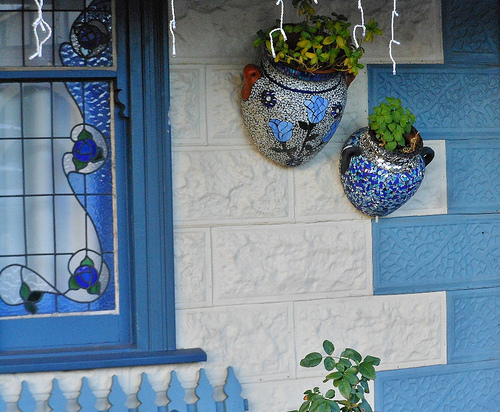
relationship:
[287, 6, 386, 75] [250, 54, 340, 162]
plants in vase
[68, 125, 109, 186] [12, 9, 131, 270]
flowers on window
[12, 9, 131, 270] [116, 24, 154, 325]
window has sill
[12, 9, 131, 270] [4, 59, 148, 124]
window has panes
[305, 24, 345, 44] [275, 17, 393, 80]
leaves on plant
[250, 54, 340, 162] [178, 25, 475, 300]
vase on wall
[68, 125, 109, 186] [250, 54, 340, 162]
flowers in vase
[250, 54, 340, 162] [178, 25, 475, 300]
vase mounted on wall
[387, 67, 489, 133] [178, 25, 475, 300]
tile on wall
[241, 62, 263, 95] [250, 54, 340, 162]
handle on vase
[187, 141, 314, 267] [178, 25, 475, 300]
bricks on wall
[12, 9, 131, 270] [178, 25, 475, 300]
window on wall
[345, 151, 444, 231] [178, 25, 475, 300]
pot on wall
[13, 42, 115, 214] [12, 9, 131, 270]
decoration on window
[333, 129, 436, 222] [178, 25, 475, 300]
pot on wall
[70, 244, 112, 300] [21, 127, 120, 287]
rose on glass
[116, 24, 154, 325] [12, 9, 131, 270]
sill on window